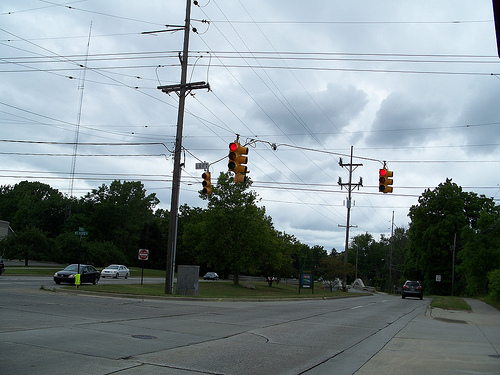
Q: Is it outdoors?
A: Yes, it is outdoors.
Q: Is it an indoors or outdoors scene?
A: It is outdoors.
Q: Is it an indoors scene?
A: No, it is outdoors.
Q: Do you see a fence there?
A: No, there are no fences.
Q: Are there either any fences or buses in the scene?
A: No, there are no fences or buses.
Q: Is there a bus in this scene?
A: No, there are no buses.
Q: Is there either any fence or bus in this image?
A: No, there are no buses or fences.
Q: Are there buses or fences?
A: No, there are no buses or fences.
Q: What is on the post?
A: The sign is on the post.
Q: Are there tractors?
A: No, there are no tractors.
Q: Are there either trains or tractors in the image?
A: No, there are no tractors or trains.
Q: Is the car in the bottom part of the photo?
A: Yes, the car is in the bottom of the image.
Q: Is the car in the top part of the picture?
A: No, the car is in the bottom of the image.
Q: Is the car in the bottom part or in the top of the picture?
A: The car is in the bottom of the image.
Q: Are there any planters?
A: No, there are no planters.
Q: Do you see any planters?
A: No, there are no planters.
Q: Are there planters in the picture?
A: No, there are no planters.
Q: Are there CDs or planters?
A: No, there are no planters or cds.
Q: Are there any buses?
A: No, there are no buses.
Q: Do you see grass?
A: Yes, there is grass.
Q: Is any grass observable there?
A: Yes, there is grass.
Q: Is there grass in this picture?
A: Yes, there is grass.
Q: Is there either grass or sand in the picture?
A: Yes, there is grass.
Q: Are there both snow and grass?
A: No, there is grass but no snow.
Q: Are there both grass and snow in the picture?
A: No, there is grass but no snow.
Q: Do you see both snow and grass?
A: No, there is grass but no snow.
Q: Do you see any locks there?
A: No, there are no locks.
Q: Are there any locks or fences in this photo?
A: No, there are no locks or fences.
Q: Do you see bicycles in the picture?
A: No, there are no bicycles.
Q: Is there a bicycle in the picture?
A: No, there are no bicycles.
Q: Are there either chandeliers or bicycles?
A: No, there are no bicycles or chandeliers.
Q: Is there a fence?
A: No, there are no fences.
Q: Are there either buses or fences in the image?
A: No, there are no fences or buses.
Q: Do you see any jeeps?
A: No, there are no jeeps.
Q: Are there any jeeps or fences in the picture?
A: No, there are no jeeps or fences.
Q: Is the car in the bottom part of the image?
A: Yes, the car is in the bottom of the image.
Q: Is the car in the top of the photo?
A: No, the car is in the bottom of the image.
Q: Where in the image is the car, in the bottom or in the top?
A: The car is in the bottom of the image.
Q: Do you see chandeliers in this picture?
A: No, there are no chandeliers.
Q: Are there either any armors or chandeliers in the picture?
A: No, there are no chandeliers or armors.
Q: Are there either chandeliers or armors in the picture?
A: No, there are no chandeliers or armors.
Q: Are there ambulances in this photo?
A: No, there are no ambulances.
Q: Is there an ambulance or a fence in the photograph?
A: No, there are no ambulances or fences.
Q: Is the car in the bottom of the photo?
A: Yes, the car is in the bottom of the image.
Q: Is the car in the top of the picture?
A: No, the car is in the bottom of the image.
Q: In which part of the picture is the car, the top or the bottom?
A: The car is in the bottom of the image.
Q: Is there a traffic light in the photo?
A: Yes, there is a traffic light.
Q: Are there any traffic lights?
A: Yes, there is a traffic light.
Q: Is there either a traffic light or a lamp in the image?
A: Yes, there is a traffic light.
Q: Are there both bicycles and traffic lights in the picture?
A: No, there is a traffic light but no bicycles.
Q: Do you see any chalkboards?
A: No, there are no chalkboards.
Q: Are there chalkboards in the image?
A: No, there are no chalkboards.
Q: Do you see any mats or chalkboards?
A: No, there are no chalkboards or mats.